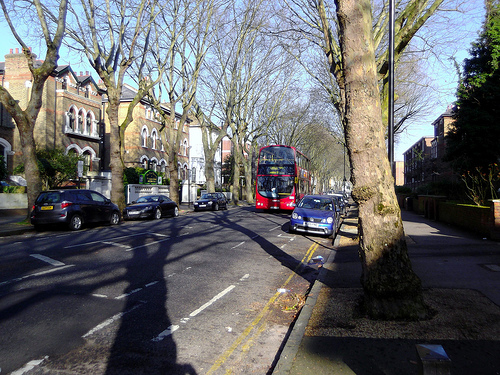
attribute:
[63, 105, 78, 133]
window — arched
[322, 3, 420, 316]
tree — leaning to the left, large, leafless, big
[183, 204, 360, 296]
shadow — long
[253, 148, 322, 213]
bus — red colored, tall, red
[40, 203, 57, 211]
license plate — gold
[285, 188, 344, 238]
car — blue, parked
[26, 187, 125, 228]
car — black, parked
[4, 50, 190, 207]
building — brick, white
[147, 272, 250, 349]
line — white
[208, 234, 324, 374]
line — yellow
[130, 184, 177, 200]
fence — white